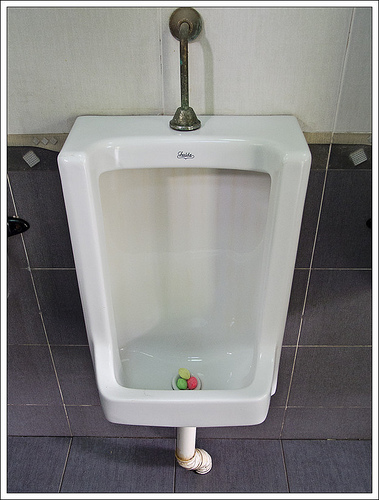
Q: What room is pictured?
A: It is a bathroom.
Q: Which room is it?
A: It is a bathroom.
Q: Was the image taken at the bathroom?
A: Yes, it was taken in the bathroom.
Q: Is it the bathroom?
A: Yes, it is the bathroom.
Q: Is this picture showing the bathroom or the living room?
A: It is showing the bathroom.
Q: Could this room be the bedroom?
A: No, it is the bathroom.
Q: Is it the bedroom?
A: No, it is the bathroom.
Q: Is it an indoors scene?
A: Yes, it is indoors.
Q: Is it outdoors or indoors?
A: It is indoors.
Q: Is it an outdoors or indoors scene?
A: It is indoors.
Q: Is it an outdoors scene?
A: No, it is indoors.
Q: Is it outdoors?
A: No, it is indoors.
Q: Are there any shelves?
A: No, there are no shelves.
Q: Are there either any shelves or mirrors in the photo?
A: No, there are no shelves or mirrors.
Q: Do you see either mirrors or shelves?
A: No, there are no shelves or mirrors.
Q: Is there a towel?
A: No, there are no towels.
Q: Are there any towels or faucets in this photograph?
A: No, there are no towels or faucets.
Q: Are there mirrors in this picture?
A: No, there are no mirrors.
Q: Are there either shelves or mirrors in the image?
A: No, there are no mirrors or shelves.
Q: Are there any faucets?
A: No, there are no faucets.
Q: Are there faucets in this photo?
A: No, there are no faucets.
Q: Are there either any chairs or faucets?
A: No, there are no faucets or chairs.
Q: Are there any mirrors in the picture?
A: No, there are no mirrors.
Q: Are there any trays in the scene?
A: No, there are no trays.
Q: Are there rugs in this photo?
A: No, there are no rugs.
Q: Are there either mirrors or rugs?
A: No, there are no rugs or mirrors.